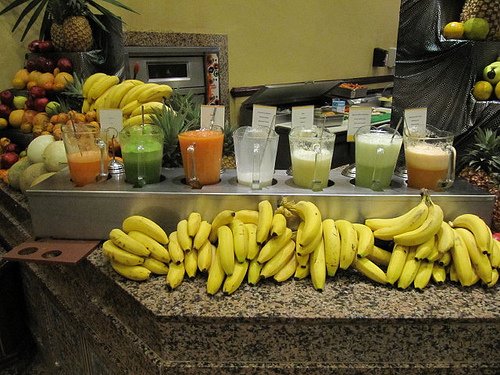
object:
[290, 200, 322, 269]
banana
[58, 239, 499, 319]
counter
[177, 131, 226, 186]
liquid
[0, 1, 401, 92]
wall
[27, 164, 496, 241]
bin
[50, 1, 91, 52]
pineapple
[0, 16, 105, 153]
shelf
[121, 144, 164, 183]
juice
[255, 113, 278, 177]
stirrer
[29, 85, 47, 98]
mango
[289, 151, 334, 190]
smoothy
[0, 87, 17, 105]
apple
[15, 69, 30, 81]
orange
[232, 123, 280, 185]
pitcher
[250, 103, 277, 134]
sign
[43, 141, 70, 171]
melon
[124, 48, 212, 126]
oven